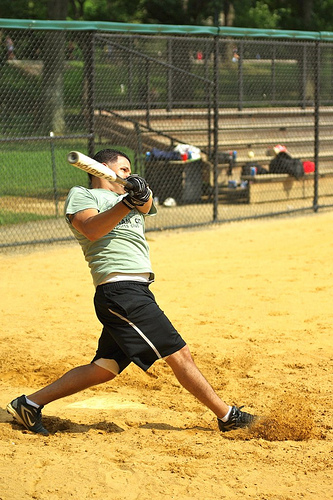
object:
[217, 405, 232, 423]
sock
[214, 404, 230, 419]
ankle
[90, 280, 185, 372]
shorts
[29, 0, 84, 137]
tree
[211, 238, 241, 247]
dirt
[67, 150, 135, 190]
bat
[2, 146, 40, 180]
grass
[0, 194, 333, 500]
ground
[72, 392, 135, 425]
home base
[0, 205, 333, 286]
field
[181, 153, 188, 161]
cup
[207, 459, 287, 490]
dirt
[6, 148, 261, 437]
man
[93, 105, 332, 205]
bleacher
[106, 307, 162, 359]
stripe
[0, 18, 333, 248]
fence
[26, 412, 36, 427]
logo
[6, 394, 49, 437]
cleats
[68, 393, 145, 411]
homeplate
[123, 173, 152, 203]
gloves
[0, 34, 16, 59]
person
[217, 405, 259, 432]
foot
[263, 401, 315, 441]
dirt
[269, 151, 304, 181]
bag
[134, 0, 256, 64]
green top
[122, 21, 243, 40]
top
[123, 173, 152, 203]
hands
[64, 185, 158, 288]
shirt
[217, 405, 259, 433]
cleats